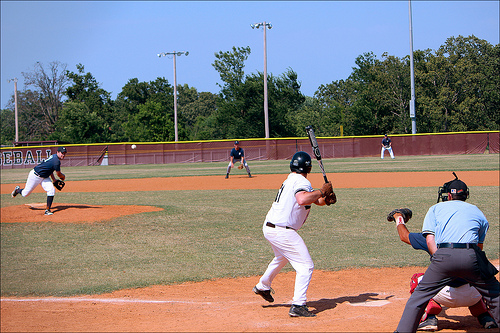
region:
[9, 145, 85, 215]
pitcher throwing ball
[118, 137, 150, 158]
ball thrown by pitcher in mid air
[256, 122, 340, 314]
batter takes stance to swing at ball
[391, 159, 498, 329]
umpire getting ready just in case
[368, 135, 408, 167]
baseball player hoping the ball goes his way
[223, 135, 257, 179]
baseball player getting ready for the batter to throw ball his way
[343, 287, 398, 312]
if the player can run the diamond once and make it back to this plate, home run.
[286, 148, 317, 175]
helmet for protection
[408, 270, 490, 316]
knee pads/shin pads for protection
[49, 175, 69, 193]
baseball mitt for catching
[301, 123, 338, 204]
a baseball bat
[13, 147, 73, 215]
a baseball player pitching the ball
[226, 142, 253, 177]
a man in a blue shirt waiting to catch the ball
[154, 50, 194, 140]
a light pole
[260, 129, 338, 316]
the batter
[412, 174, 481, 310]
the ump watching the game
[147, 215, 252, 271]
grass in the baseball field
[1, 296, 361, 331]
the red sand of the baseball field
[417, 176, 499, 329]
a man wearing a blue shirt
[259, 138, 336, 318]
baseball player wearing a black helmet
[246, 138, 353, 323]
a baseball player holding a bat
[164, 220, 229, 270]
green grass of the baseball field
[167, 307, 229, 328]
brown dirt of the baseball diamond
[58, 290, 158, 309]
white line on the baseball diamond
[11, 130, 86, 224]
a pitcher wearing a green and white uniform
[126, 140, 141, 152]
a white baseball in midair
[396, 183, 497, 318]
an umpire wearing a blue shirt and grey pants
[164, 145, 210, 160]
red fence of the baseball field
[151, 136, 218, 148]
yellow trim on the red fence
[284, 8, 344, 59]
clear blue skies over the baseball field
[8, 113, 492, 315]
a baseball game is being played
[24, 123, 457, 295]
two separate teams are on the field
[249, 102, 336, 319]
the man is up at bat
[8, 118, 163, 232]
this man is pitching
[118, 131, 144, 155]
the baseball has been thrown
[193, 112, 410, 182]
two of the outfielders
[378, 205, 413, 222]
the player has a mitt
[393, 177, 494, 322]
the umpire is behind the catcher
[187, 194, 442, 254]
this portion of the playing field is grass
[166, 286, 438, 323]
this portion of the playing field is dirt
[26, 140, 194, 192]
A man is throwing a ball.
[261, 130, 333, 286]
A man is holding a baseball bat.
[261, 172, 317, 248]
A man is wearing a white shirt.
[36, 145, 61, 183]
A man is wearing a blue shirt.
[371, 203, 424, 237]
A person is holding a catchers mit.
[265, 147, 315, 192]
A man is wearing a helmet.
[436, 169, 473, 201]
A man is wearing a black hat.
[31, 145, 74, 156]
A man is wearing a blue hat.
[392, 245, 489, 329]
A man is wearing grey pants.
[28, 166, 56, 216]
A man is wearing white pants.